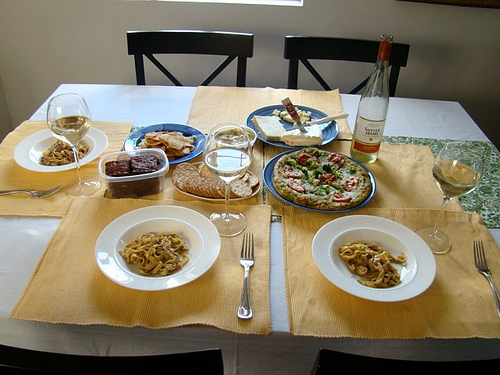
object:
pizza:
[263, 147, 377, 213]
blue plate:
[262, 148, 377, 213]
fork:
[237, 232, 255, 319]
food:
[118, 232, 189, 275]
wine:
[432, 161, 480, 196]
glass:
[415, 140, 483, 255]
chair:
[125, 31, 253, 88]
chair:
[283, 36, 411, 97]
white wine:
[350, 33, 396, 164]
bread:
[251, 116, 286, 141]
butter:
[280, 124, 322, 146]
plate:
[246, 104, 339, 148]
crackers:
[170, 161, 262, 202]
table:
[0, 84, 500, 375]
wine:
[205, 149, 251, 184]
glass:
[46, 92, 101, 197]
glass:
[202, 123, 257, 237]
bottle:
[347, 33, 390, 167]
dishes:
[97, 123, 258, 292]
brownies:
[97, 148, 170, 199]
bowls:
[93, 204, 437, 303]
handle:
[280, 96, 308, 133]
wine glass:
[46, 93, 102, 196]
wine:
[349, 141, 380, 163]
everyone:
[152, 169, 435, 341]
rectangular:
[98, 147, 169, 198]